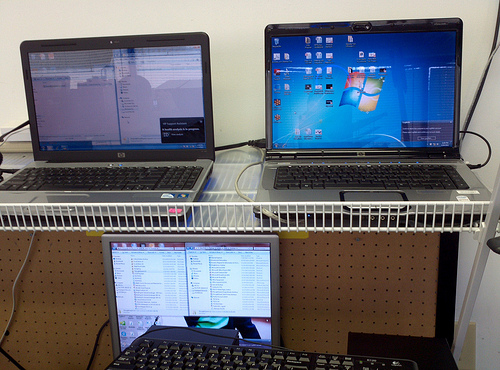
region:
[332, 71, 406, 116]
windows logo on desktop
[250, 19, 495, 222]
grey laptop on white shelf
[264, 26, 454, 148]
blue background of grey laptop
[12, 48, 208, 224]
grey laptop with multiple windows open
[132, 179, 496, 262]
white shelf with laptops on it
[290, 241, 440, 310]
brown pegboard behind screen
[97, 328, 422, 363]
black keyboard corner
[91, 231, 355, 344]
screen under two laptops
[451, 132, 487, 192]
black cord plugged into laptops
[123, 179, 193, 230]
three stickers on laptop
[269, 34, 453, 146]
windows desktop screen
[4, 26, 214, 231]
an hp laptop computer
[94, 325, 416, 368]
a black computer keyboard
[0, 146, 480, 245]
a white metal shelf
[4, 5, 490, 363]
three gray computers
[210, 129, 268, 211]
two computer wires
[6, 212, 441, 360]
brown backboard with holes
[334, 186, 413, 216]
a laptop mouse pad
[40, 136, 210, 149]
a windows operating system taskbar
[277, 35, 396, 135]
icons on a computer desktop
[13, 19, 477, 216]
Two laptops on a shelf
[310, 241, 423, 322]
Brown pegboard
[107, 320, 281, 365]
A black keyboard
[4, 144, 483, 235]
A white piece of shelving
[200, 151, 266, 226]
A plastic liner on shelving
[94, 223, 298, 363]
A monitor turned on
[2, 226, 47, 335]
A cord running up a wall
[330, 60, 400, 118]
The Windows logo visible on a screen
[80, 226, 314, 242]
Yellow tape on a pegboard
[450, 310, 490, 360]
A light switch on the wall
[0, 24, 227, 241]
laptop computer sitting on shelf.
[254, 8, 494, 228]
laptop computer sitting next to another laptop computer.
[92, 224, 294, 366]
laptop computer sitting below two laptop computers.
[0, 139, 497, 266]
Wire shelf with two laptop computers on it.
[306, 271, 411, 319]
wooden wall.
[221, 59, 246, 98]
section of white walls behind a shelf.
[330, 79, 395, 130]
section of screen on a laptop computer.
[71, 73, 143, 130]
screen background on a laptop computer.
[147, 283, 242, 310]
laptop computer screen.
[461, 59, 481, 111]
section of wire near a computer.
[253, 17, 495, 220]
A silver Windows laptop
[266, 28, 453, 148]
The screen of a laptop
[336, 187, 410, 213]
The touch pad of a laptop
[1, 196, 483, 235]
A white display case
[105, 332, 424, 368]
A black keyboard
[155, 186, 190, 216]
Labels on a new laptop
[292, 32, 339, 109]
Desktop icons on a laptop screen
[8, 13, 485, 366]
Three laptops on display in a store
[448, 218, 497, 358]
A light silver pole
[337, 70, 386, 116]
The Windows logo on the background of a laptop